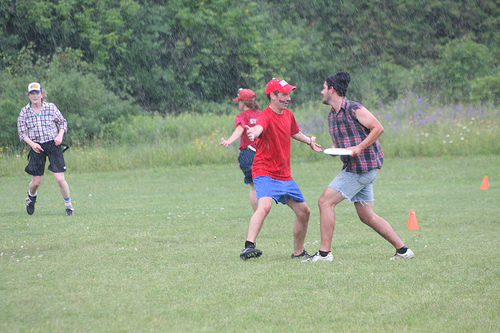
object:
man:
[298, 72, 414, 263]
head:
[319, 71, 351, 105]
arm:
[353, 101, 386, 151]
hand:
[345, 145, 363, 159]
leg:
[312, 168, 365, 254]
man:
[238, 77, 321, 261]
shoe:
[237, 247, 263, 261]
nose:
[318, 89, 326, 96]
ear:
[327, 85, 335, 95]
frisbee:
[320, 147, 357, 156]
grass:
[0, 170, 498, 332]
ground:
[0, 119, 499, 332]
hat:
[323, 72, 351, 91]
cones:
[404, 208, 420, 232]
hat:
[263, 78, 295, 94]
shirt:
[250, 104, 301, 181]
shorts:
[328, 166, 380, 205]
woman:
[217, 88, 262, 213]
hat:
[230, 88, 255, 102]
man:
[16, 81, 75, 216]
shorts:
[22, 140, 67, 177]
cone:
[478, 174, 487, 191]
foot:
[237, 245, 263, 262]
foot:
[299, 252, 335, 263]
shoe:
[300, 251, 334, 264]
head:
[264, 77, 292, 111]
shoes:
[288, 252, 312, 260]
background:
[0, 0, 499, 178]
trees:
[43, 44, 95, 79]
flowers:
[385, 94, 417, 112]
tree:
[428, 38, 499, 112]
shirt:
[325, 96, 385, 174]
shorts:
[250, 174, 307, 206]